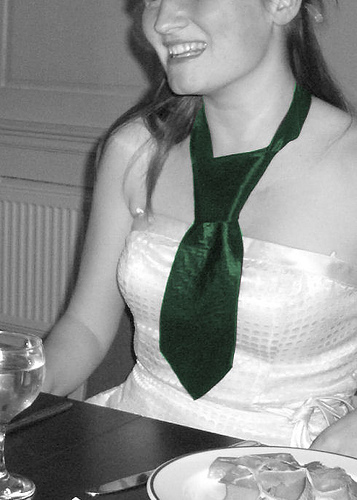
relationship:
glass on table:
[0, 327, 45, 500] [0, 391, 272, 499]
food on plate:
[211, 457, 346, 498] [146, 444, 356, 499]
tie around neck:
[158, 78, 312, 402] [201, 27, 292, 123]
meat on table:
[212, 452, 353, 497] [20, 393, 161, 496]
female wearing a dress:
[36, 0, 356, 457] [83, 212, 354, 447]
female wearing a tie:
[36, 0, 356, 457] [158, 78, 312, 402]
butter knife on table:
[72, 466, 156, 500] [1, 360, 356, 498]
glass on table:
[0, 327, 45, 500] [2, 377, 260, 499]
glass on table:
[0, 327, 45, 500] [0, 372, 349, 498]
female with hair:
[36, 0, 356, 457] [111, 0, 351, 223]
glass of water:
[0, 327, 45, 495] [1, 350, 45, 426]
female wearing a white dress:
[36, 0, 356, 457] [80, 209, 355, 451]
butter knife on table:
[67, 466, 163, 498] [7, 383, 249, 497]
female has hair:
[36, 0, 356, 457] [64, 18, 326, 235]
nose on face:
[153, 1, 190, 36] [136, 0, 305, 102]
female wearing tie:
[36, 0, 356, 457] [112, 89, 333, 278]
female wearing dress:
[36, 0, 356, 457] [83, 212, 354, 447]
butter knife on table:
[72, 466, 156, 500] [0, 391, 272, 499]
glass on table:
[0, 327, 45, 500] [78, 420, 142, 458]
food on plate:
[207, 453, 357, 499] [146, 444, 356, 499]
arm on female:
[30, 107, 158, 396] [36, 0, 356, 457]